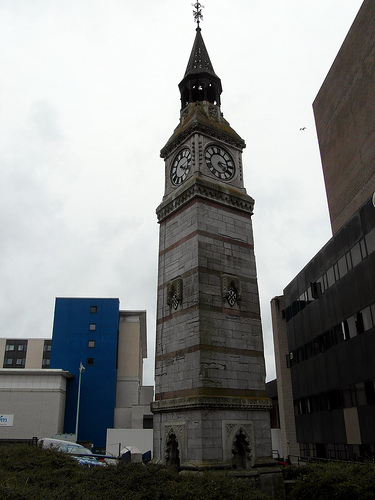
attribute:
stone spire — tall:
[150, 0, 272, 480]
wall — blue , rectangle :
[35, 293, 125, 460]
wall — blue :
[49, 292, 131, 454]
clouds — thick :
[24, 98, 71, 153]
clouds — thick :
[15, 174, 77, 231]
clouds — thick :
[101, 218, 152, 275]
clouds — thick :
[258, 172, 316, 235]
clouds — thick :
[5, 292, 49, 333]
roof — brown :
[169, 78, 240, 140]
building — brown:
[279, 184, 373, 464]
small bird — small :
[295, 120, 314, 135]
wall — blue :
[47, 293, 122, 448]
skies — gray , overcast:
[54, 190, 105, 253]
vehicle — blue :
[33, 429, 113, 474]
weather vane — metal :
[189, 0, 207, 26]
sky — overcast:
[34, 141, 107, 271]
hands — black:
[206, 154, 254, 180]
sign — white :
[0, 413, 18, 427]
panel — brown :
[333, 161, 363, 205]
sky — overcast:
[58, 71, 116, 156]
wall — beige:
[100, 425, 154, 463]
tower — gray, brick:
[151, 7, 278, 475]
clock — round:
[201, 139, 237, 182]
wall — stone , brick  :
[154, 192, 277, 432]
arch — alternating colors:
[228, 421, 253, 467]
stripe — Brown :
[146, 384, 270, 403]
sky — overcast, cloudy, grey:
[2, 4, 369, 388]